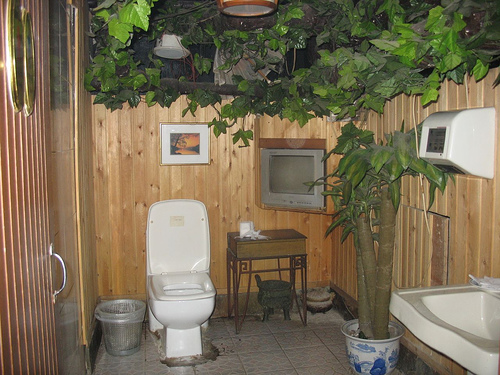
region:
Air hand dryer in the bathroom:
[417, 105, 499, 179]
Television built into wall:
[258, 147, 324, 210]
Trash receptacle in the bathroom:
[92, 298, 145, 358]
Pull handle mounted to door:
[47, 240, 68, 306]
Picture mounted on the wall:
[158, 121, 211, 164]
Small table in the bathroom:
[225, 225, 310, 334]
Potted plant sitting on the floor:
[302, 123, 450, 374]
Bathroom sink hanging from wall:
[390, 275, 499, 373]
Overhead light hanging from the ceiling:
[152, 30, 188, 60]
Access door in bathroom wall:
[388, 203, 451, 290]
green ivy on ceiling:
[84, 3, 491, 106]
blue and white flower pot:
[341, 315, 401, 372]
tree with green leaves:
[328, 127, 430, 339]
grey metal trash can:
[96, 298, 144, 353]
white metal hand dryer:
[420, 108, 495, 176]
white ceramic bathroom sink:
[393, 277, 496, 374]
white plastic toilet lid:
[146, 198, 209, 278]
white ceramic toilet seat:
[153, 273, 216, 303]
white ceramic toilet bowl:
[146, 293, 214, 360]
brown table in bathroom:
[227, 230, 309, 324]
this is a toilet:
[132, 192, 233, 356]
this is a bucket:
[85, 285, 145, 374]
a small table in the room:
[230, 199, 314, 329]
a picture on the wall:
[150, 106, 234, 171]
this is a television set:
[234, 113, 344, 239]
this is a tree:
[302, 120, 446, 372]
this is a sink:
[381, 274, 498, 371]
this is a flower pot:
[332, 320, 427, 373]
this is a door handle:
[40, 243, 75, 313]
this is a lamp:
[153, 22, 216, 79]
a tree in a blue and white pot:
[304, 118, 452, 373]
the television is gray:
[253, 141, 328, 213]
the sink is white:
[383, 272, 499, 372]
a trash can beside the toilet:
[90, 292, 150, 357]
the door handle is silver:
[46, 238, 72, 304]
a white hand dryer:
[413, 103, 494, 182]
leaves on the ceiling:
[84, 4, 494, 129]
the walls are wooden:
[88, 46, 499, 363]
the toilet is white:
[130, 195, 227, 367]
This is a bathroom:
[118, 37, 377, 330]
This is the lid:
[126, 166, 212, 276]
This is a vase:
[320, 336, 380, 358]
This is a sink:
[374, 264, 497, 336]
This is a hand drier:
[413, 101, 488, 138]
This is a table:
[190, 111, 354, 360]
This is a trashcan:
[90, 266, 131, 356]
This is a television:
[258, 100, 370, 270]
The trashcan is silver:
[101, 259, 142, 374]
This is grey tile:
[233, 337, 301, 372]